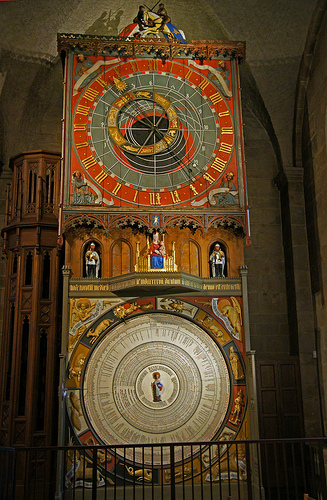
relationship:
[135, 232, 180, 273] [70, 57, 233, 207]
throne front of clock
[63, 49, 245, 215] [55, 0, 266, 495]
clock on tower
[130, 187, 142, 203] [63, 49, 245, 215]
number on clock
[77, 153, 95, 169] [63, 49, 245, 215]
number on clock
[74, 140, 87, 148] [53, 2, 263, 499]
number on clock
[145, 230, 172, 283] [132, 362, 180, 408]
woman in middle of circle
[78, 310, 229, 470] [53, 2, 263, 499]
silver portion of clock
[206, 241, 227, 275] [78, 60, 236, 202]
statue on clock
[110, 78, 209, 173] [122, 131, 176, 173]
hands with arrows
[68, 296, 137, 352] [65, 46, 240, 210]
images around clock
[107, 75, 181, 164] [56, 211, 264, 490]
ring around clock